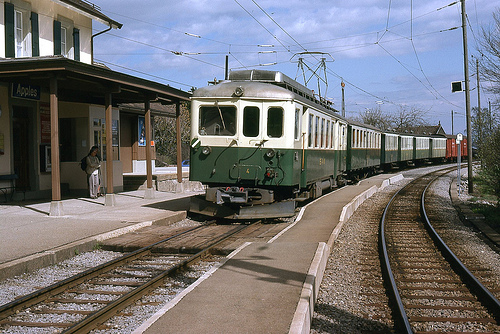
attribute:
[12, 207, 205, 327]
tracks — train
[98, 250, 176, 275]
tracks — train